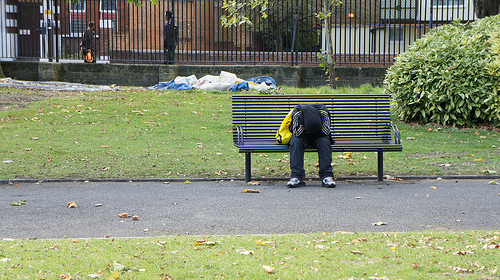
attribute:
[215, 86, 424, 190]
bench — black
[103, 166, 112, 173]
leaf — brown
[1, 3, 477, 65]
metalfence — black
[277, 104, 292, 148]
yellow bag — yellow 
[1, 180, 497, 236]
path — concrete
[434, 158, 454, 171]
leaf — brown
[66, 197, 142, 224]
leaves — brown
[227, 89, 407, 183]
bench — stone, black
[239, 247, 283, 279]
leaves — brown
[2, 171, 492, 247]
ground — gray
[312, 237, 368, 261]
leaves — brown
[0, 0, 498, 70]
fence — black, metal